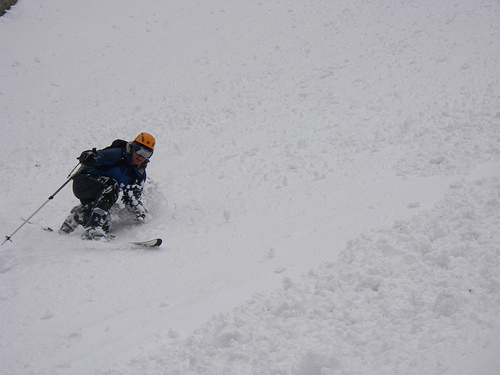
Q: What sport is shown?
A: Skiing.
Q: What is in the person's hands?
A: Ski poles.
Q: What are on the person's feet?
A: Skis.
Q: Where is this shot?
A: Slopes.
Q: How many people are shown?
A: 1.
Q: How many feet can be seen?
A: 2.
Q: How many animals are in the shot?
A: 0.